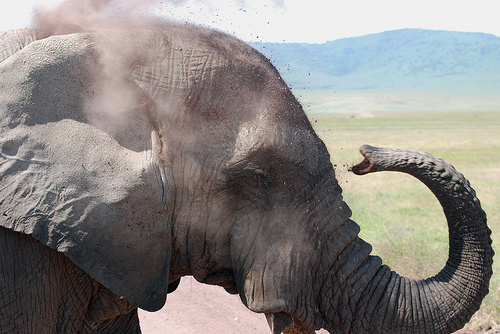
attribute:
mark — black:
[127, 223, 133, 229]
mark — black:
[106, 159, 111, 163]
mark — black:
[127, 200, 131, 203]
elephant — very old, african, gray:
[2, 24, 496, 334]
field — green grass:
[291, 91, 500, 333]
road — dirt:
[137, 274, 273, 333]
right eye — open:
[225, 169, 266, 190]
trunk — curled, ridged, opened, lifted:
[303, 139, 494, 334]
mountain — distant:
[246, 28, 498, 95]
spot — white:
[152, 292, 160, 299]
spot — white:
[116, 271, 125, 276]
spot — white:
[99, 263, 109, 271]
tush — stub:
[263, 309, 297, 334]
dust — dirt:
[28, 2, 186, 137]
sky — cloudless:
[153, 1, 498, 45]